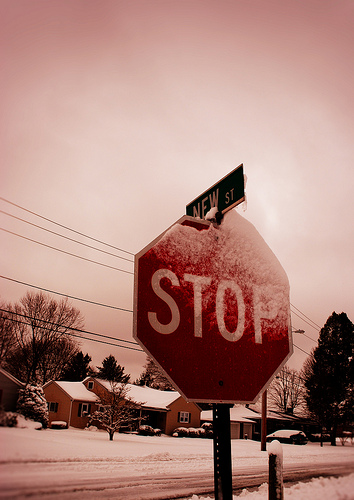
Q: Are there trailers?
A: No, there are no trailers.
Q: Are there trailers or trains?
A: No, there are no trailers or trains.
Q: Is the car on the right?
A: Yes, the car is on the right of the image.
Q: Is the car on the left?
A: No, the car is on the right of the image.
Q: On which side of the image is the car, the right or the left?
A: The car is on the right of the image.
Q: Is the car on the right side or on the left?
A: The car is on the right of the image.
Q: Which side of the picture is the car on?
A: The car is on the right of the image.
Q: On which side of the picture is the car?
A: The car is on the right of the image.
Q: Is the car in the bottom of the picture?
A: Yes, the car is in the bottom of the image.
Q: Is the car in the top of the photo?
A: No, the car is in the bottom of the image.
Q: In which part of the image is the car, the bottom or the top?
A: The car is in the bottom of the image.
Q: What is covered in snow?
A: The car is covered in snow.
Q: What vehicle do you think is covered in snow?
A: The vehicle is a car.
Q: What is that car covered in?
A: The car is covered in snow.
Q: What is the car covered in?
A: The car is covered in snow.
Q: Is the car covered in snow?
A: Yes, the car is covered in snow.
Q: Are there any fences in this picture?
A: No, there are no fences.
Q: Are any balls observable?
A: No, there are no balls.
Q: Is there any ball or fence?
A: No, there are no balls or fences.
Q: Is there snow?
A: Yes, there is snow.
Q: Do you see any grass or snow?
A: Yes, there is snow.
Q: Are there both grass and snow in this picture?
A: No, there is snow but no grass.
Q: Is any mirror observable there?
A: No, there are no mirrors.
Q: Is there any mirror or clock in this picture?
A: No, there are no mirrors or clocks.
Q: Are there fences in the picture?
A: No, there are no fences.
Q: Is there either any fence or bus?
A: No, there are no fences or buses.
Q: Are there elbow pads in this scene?
A: No, there are no elbow pads.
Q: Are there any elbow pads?
A: No, there are no elbow pads.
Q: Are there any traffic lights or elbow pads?
A: No, there are no elbow pads or traffic lights.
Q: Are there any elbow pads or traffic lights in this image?
A: No, there are no elbow pads or traffic lights.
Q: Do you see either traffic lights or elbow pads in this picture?
A: No, there are no elbow pads or traffic lights.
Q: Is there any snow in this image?
A: Yes, there is snow.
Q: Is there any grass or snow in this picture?
A: Yes, there is snow.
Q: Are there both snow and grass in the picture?
A: No, there is snow but no grass.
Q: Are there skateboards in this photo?
A: No, there are no skateboards.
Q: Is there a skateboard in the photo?
A: No, there are no skateboards.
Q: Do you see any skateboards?
A: No, there are no skateboards.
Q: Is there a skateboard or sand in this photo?
A: No, there are no skateboards or sand.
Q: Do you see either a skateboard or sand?
A: No, there are no skateboards or sand.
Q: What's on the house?
A: The snow is on the house.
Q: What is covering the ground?
A: The snow is covering the ground.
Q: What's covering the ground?
A: The snow is covering the ground.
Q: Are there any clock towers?
A: No, there are no clock towers.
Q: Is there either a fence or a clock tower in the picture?
A: No, there are no clock towers or fences.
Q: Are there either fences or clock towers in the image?
A: No, there are no clock towers or fences.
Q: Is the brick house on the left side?
A: Yes, the house is on the left of the image.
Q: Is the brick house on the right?
A: No, the house is on the left of the image.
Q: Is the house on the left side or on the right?
A: The house is on the left of the image.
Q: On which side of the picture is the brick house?
A: The house is on the left of the image.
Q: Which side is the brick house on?
A: The house is on the left of the image.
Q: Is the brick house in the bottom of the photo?
A: Yes, the house is in the bottom of the image.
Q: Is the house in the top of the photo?
A: No, the house is in the bottom of the image.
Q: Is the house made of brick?
A: Yes, the house is made of brick.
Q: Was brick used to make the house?
A: Yes, the house is made of brick.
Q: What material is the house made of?
A: The house is made of brick.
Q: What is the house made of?
A: The house is made of brick.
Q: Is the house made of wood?
A: No, the house is made of brick.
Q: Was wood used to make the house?
A: No, the house is made of brick.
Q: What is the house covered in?
A: The house is covered in snow.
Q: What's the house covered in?
A: The house is covered in snow.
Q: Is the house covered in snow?
A: Yes, the house is covered in snow.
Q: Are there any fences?
A: No, there are no fences.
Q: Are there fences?
A: No, there are no fences.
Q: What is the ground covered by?
A: The ground is covered by the snow.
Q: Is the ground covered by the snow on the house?
A: Yes, the ground is covered by the snow.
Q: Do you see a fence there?
A: No, there are no fences.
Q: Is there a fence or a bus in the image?
A: No, there are no fences or buses.